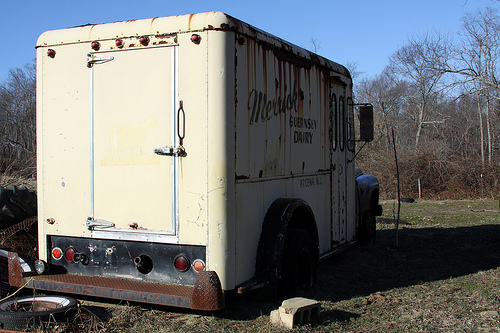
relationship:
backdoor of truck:
[76, 39, 197, 250] [5, 6, 406, 305]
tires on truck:
[273, 225, 322, 309] [5, 6, 406, 305]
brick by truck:
[258, 290, 327, 331] [5, 6, 406, 305]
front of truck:
[357, 164, 391, 239] [5, 6, 406, 305]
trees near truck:
[386, 41, 495, 200] [5, 6, 406, 305]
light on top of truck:
[43, 30, 204, 56] [5, 6, 406, 305]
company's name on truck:
[248, 59, 306, 126] [5, 6, 406, 305]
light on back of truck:
[43, 30, 204, 56] [5, 6, 406, 305]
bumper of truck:
[0, 263, 228, 312] [5, 6, 406, 305]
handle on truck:
[149, 138, 193, 159] [5, 6, 406, 305]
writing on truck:
[244, 56, 326, 170] [5, 6, 406, 305]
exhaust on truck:
[123, 253, 161, 275] [5, 6, 406, 305]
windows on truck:
[330, 90, 352, 148] [5, 6, 406, 305]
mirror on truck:
[350, 97, 380, 145] [5, 6, 406, 305]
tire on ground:
[3, 295, 74, 328] [83, 308, 189, 333]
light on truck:
[171, 253, 197, 276] [5, 6, 406, 305]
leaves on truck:
[248, 207, 269, 276] [5, 6, 406, 305]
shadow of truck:
[369, 211, 491, 293] [5, 6, 406, 305]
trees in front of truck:
[386, 41, 495, 200] [5, 6, 406, 305]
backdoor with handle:
[76, 39, 197, 250] [149, 138, 193, 159]